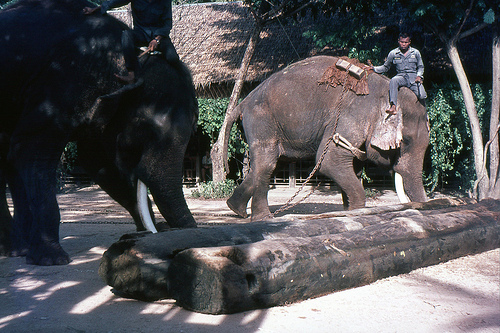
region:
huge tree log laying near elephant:
[169, 201, 496, 313]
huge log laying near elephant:
[100, 188, 478, 298]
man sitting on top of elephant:
[375, 30, 428, 117]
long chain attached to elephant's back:
[246, 64, 363, 225]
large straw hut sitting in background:
[89, 0, 341, 194]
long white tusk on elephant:
[134, 177, 163, 236]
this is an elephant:
[220, 45, 466, 227]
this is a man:
[373, 26, 430, 119]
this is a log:
[169, 169, 499, 320]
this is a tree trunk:
[208, 25, 252, 199]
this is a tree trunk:
[439, 38, 488, 195]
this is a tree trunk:
[485, 33, 497, 190]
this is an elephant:
[8, 8, 205, 270]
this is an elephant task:
[382, 160, 413, 212]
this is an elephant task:
[126, 171, 167, 238]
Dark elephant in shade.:
[4, 0, 205, 263]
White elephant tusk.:
[127, 182, 163, 237]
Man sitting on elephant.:
[217, 32, 433, 214]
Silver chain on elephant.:
[246, 65, 354, 225]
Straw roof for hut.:
[101, 8, 256, 89]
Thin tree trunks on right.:
[447, 5, 497, 195]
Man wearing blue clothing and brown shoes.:
[378, 34, 430, 112]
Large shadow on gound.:
[1, 261, 251, 331]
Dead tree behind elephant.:
[201, 3, 266, 195]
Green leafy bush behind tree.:
[427, 98, 480, 190]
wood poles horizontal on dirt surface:
[101, 196, 498, 314]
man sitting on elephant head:
[219, 34, 431, 219]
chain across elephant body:
[254, 70, 355, 219]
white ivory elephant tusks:
[135, 181, 160, 233]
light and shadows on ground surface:
[1, 190, 498, 330]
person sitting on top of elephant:
[2, 0, 197, 265]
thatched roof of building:
[111, 4, 318, 83]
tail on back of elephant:
[221, 106, 241, 176]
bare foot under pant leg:
[384, 77, 403, 115]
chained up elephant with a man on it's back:
[218, 55, 436, 217]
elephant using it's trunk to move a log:
[5, 5, 212, 267]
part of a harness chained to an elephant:
[327, 128, 366, 161]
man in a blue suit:
[364, 33, 429, 116]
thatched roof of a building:
[91, 1, 343, 91]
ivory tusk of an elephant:
[132, 180, 159, 233]